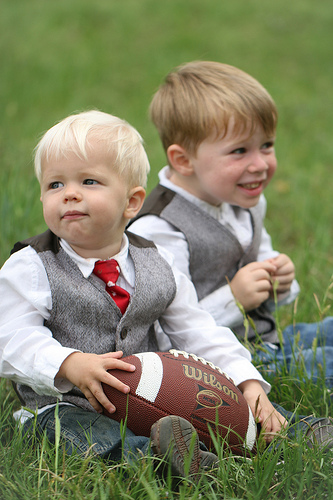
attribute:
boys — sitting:
[1, 59, 325, 490]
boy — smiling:
[139, 54, 329, 394]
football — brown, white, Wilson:
[94, 350, 260, 458]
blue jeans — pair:
[252, 314, 332, 380]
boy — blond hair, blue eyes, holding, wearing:
[0, 109, 295, 477]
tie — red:
[90, 256, 131, 314]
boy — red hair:
[154, 70, 300, 313]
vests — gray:
[18, 187, 265, 408]